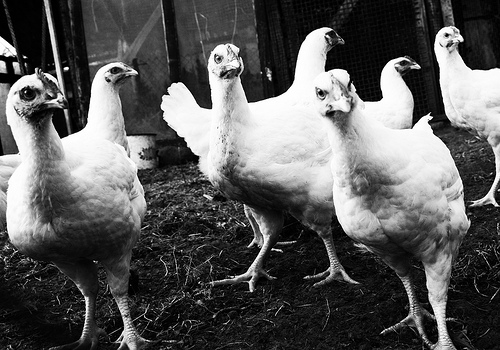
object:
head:
[207, 43, 245, 80]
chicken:
[346, 55, 422, 130]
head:
[305, 26, 347, 48]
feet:
[205, 267, 279, 292]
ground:
[0, 124, 499, 350]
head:
[392, 55, 422, 74]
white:
[386, 133, 435, 164]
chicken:
[311, 68, 471, 348]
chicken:
[207, 44, 362, 293]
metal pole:
[43, 0, 74, 135]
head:
[315, 68, 359, 120]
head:
[7, 68, 75, 127]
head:
[95, 61, 139, 86]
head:
[433, 25, 462, 51]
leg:
[56, 261, 99, 295]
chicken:
[6, 67, 152, 349]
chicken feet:
[110, 329, 160, 349]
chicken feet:
[204, 268, 279, 294]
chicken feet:
[376, 304, 458, 348]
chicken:
[433, 25, 498, 208]